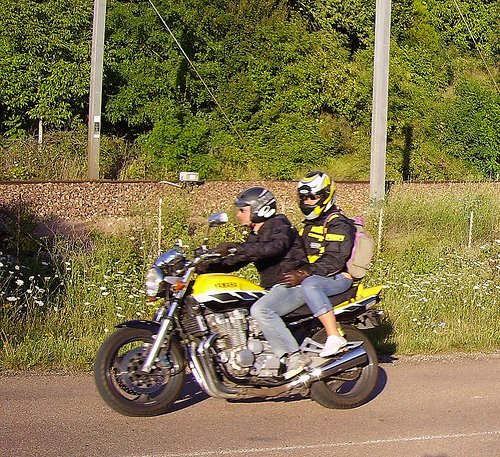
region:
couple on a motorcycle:
[97, 166, 414, 412]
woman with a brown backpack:
[294, 163, 379, 364]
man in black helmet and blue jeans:
[195, 177, 307, 379]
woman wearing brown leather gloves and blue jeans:
[282, 171, 347, 363]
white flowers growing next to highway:
[14, 260, 112, 354]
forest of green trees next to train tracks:
[180, 9, 358, 146]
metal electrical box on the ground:
[155, 148, 208, 205]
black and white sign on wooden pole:
[92, 110, 108, 142]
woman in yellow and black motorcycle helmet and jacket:
[291, 148, 369, 275]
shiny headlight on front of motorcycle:
[141, 256, 178, 299]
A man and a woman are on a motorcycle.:
[86, 163, 399, 424]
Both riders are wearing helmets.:
[217, 168, 350, 232]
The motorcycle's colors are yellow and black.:
[86, 206, 397, 420]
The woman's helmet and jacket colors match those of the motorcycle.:
[283, 166, 361, 293]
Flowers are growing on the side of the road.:
[0, 213, 498, 340]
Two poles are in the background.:
[76, 0, 402, 214]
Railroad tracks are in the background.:
[0, 146, 499, 201]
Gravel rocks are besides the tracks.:
[0, 178, 498, 219]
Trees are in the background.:
[0, 0, 498, 182]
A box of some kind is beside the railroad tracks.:
[150, 162, 207, 194]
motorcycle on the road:
[101, 273, 409, 408]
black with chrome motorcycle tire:
[92, 323, 189, 413]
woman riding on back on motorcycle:
[297, 184, 354, 370]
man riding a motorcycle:
[204, 187, 324, 378]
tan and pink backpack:
[338, 210, 378, 281]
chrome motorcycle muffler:
[177, 327, 370, 399]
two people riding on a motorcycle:
[92, 164, 394, 421]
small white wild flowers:
[396, 269, 498, 354]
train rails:
[2, 145, 84, 207]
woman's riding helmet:
[291, 171, 338, 222]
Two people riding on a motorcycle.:
[184, 187, 379, 453]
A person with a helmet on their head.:
[290, 171, 355, 246]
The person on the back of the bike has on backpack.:
[338, 205, 382, 287]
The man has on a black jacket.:
[225, 219, 302, 282]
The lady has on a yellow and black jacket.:
[290, 216, 375, 278]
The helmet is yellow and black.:
[292, 180, 349, 225]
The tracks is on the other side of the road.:
[11, 151, 406, 218]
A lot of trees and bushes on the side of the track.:
[137, 4, 494, 175]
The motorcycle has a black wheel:
[87, 316, 194, 425]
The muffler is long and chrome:
[187, 339, 376, 398]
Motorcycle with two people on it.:
[93, 170, 387, 419]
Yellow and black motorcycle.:
[94, 214, 391, 418]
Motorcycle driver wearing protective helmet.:
[194, 184, 311, 379]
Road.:
[0, 350, 498, 455]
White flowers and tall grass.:
[0, 248, 92, 370]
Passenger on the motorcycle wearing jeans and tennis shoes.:
[281, 167, 376, 357]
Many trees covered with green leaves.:
[1, 0, 496, 180]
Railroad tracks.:
[0, 170, 498, 186]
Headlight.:
[141, 262, 164, 298]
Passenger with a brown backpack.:
[280, 169, 377, 354]